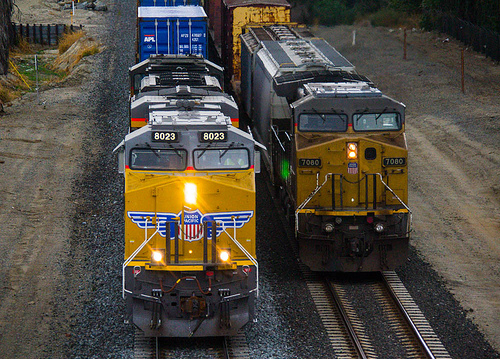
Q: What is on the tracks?
A: Yellow train 8023.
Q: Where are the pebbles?
A: Near the tracks.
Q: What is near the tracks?
A: Pebbles.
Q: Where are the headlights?
A: On the front of the trains.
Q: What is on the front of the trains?
A: Headlights.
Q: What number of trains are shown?
A: Two.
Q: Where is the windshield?
A: On the front of the train.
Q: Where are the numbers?
A: Near the top of the train.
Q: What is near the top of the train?
A: Numbers.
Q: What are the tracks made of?
A: Steel.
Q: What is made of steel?
A: The tracks.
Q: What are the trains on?
A: Train tracks.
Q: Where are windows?
A: On the trains.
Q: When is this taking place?
A: Daytime.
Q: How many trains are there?
A: Two.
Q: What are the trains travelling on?
A: Train tracks.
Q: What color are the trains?
A: Yellow, grey and blue.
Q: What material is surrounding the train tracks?
A: Gravel.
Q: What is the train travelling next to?
A: Dirt ground.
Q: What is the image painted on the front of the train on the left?
A: Bird with wings.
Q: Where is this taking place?
A: Train tracks with two trains passing by.